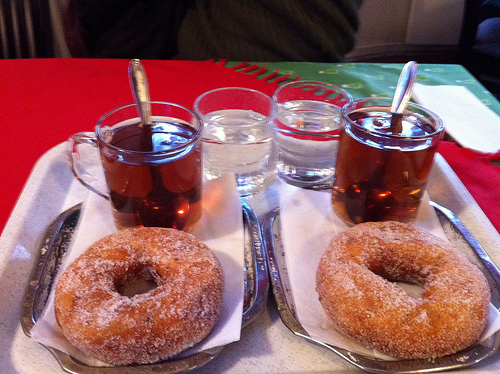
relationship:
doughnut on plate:
[60, 224, 224, 372] [21, 191, 275, 373]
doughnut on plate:
[313, 216, 495, 363] [263, 194, 499, 373]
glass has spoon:
[56, 98, 209, 245] [126, 54, 194, 236]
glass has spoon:
[328, 94, 445, 233] [342, 57, 418, 225]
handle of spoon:
[127, 53, 168, 190] [126, 54, 194, 236]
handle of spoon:
[374, 56, 419, 184] [342, 57, 418, 225]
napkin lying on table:
[404, 78, 500, 161] [2, 54, 500, 373]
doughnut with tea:
[60, 224, 224, 372] [97, 116, 210, 238]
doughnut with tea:
[313, 216, 495, 363] [337, 117, 439, 230]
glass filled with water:
[192, 89, 279, 212] [198, 111, 272, 198]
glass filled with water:
[270, 76, 359, 196] [275, 98, 346, 190]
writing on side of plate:
[251, 226, 265, 274] [21, 191, 275, 373]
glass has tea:
[56, 98, 209, 245] [97, 116, 210, 238]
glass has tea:
[328, 94, 445, 233] [337, 117, 439, 230]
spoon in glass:
[126, 54, 194, 236] [56, 98, 209, 245]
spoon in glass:
[342, 57, 418, 225] [328, 94, 445, 233]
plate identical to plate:
[21, 191, 275, 373] [263, 194, 499, 373]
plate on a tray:
[21, 191, 275, 373] [0, 128, 496, 373]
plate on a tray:
[263, 194, 499, 373] [0, 128, 496, 373]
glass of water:
[192, 89, 279, 212] [198, 111, 272, 198]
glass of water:
[270, 76, 359, 196] [275, 98, 346, 190]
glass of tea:
[56, 98, 209, 245] [97, 116, 210, 238]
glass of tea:
[328, 94, 445, 233] [337, 117, 439, 230]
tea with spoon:
[97, 116, 210, 238] [126, 54, 194, 236]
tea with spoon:
[337, 117, 439, 230] [342, 57, 418, 225]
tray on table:
[0, 128, 496, 373] [2, 54, 500, 373]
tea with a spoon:
[97, 116, 210, 238] [126, 54, 194, 236]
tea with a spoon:
[337, 117, 439, 230] [342, 57, 418, 225]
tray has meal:
[0, 128, 496, 373] [25, 51, 277, 373]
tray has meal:
[0, 128, 496, 373] [263, 194, 499, 373]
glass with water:
[192, 89, 279, 212] [198, 111, 272, 198]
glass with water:
[270, 76, 359, 196] [275, 98, 346, 190]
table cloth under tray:
[1, 56, 499, 365] [0, 128, 496, 373]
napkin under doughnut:
[272, 175, 499, 363] [313, 216, 495, 363]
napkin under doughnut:
[29, 173, 250, 358] [60, 224, 224, 372]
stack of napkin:
[405, 77, 499, 158] [404, 78, 500, 161]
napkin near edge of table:
[404, 78, 500, 161] [2, 54, 500, 373]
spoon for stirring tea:
[126, 54, 194, 236] [97, 116, 210, 238]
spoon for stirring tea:
[342, 57, 418, 225] [337, 117, 439, 230]